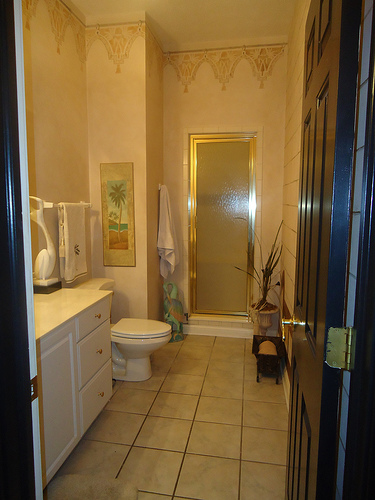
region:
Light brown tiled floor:
[168, 351, 272, 486]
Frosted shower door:
[180, 128, 259, 324]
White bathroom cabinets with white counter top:
[27, 280, 119, 493]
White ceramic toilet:
[71, 270, 173, 388]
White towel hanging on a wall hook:
[146, 167, 178, 283]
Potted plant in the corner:
[234, 204, 280, 334]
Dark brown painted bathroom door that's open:
[271, 0, 348, 498]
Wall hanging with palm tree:
[91, 153, 141, 273]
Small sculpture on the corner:
[153, 276, 190, 340]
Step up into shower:
[189, 305, 248, 356]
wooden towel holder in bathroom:
[245, 328, 294, 388]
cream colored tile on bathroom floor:
[113, 401, 224, 454]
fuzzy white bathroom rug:
[50, 470, 141, 495]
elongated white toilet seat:
[110, 305, 173, 389]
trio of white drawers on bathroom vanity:
[71, 294, 124, 422]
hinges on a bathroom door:
[322, 325, 372, 376]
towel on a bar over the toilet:
[49, 195, 100, 284]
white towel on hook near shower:
[154, 176, 186, 282]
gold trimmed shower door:
[179, 123, 264, 328]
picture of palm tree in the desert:
[96, 159, 141, 275]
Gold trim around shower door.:
[182, 113, 272, 233]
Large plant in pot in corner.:
[250, 270, 289, 355]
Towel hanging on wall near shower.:
[157, 227, 190, 306]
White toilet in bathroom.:
[117, 305, 178, 417]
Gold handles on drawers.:
[95, 309, 121, 412]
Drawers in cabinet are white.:
[59, 316, 130, 436]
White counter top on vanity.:
[52, 301, 81, 328]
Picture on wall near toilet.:
[100, 227, 139, 269]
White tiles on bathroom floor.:
[151, 378, 209, 486]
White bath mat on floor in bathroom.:
[73, 468, 127, 497]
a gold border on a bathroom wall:
[81, 16, 146, 72]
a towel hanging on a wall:
[154, 178, 181, 285]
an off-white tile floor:
[109, 340, 280, 499]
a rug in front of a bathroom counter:
[44, 461, 150, 499]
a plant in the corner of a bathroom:
[244, 216, 285, 340]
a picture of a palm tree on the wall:
[100, 154, 138, 271]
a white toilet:
[69, 272, 183, 383]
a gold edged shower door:
[174, 125, 267, 327]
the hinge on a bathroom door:
[318, 318, 365, 373]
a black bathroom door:
[281, 1, 355, 497]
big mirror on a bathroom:
[183, 120, 262, 330]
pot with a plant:
[237, 232, 283, 335]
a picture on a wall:
[86, 153, 147, 277]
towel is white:
[55, 191, 91, 289]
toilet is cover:
[113, 309, 177, 389]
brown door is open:
[272, 1, 363, 499]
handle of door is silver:
[272, 309, 303, 346]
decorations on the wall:
[167, 42, 289, 114]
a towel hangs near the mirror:
[155, 173, 182, 287]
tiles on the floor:
[110, 375, 280, 490]